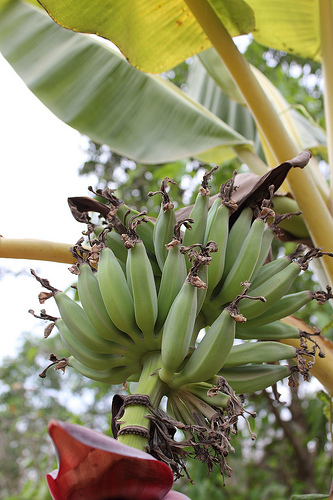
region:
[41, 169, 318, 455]
small green plant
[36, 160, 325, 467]
tipburn of green plant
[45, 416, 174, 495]
red leaf of plant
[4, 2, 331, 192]
big plantan leaves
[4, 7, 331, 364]
yellow branches with big leaves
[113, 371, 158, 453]
green thin stem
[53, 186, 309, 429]
green bunch of bananas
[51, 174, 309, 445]
green bunch of bananas with buntips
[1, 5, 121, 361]
white sky in the back of plants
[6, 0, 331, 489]
banana tree in a sunny day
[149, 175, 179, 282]
The banana is not yet ready to pick.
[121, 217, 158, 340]
The banana is not yet ready to pick.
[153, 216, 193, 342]
The banana is not yet ready to pick.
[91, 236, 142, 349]
The banana is not yet ready to pick.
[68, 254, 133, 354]
The banana is not yet ready to pick.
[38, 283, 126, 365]
The banana is not yet ready to pick.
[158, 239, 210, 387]
The banana is not yet ready to pick.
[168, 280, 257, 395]
The banana is not yet ready to pick.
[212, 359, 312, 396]
The banana is not yet ready to pick.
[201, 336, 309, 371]
The banana is not yet ready to pick.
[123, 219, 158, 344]
banana on a tree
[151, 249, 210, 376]
banana on a tree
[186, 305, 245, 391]
banana on a tree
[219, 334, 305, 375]
banana on a tree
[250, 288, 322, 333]
banana on a tree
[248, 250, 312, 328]
banana on a tree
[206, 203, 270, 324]
banana on a tree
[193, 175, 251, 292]
banana on a tree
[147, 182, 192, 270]
banana on a tree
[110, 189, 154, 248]
banana on a tree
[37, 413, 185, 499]
red leaf at bottom of tree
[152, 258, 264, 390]
first cluster of bananas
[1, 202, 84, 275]
Yellow horizontal stem on left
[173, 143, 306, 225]
Dried leaf on top right of bananas.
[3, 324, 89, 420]
Blurred leaves in the background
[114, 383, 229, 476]
Dried branches on bottom of bunch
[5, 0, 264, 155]
Large yellow and green leaves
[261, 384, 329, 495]
Tree in background behind bunches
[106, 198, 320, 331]
Top bunch of bananas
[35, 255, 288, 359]
Middle bunch of bananas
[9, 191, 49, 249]
The sky is white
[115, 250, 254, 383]
The fruit is growing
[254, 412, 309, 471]
The leaves are green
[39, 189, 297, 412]
The fruit are together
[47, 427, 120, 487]
The leaf is red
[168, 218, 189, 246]
Dark objects are at the end of the fruit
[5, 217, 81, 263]
The vine is yellow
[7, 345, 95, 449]
Trees are in the back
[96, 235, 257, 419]
The fruit is green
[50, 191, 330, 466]
Many bananas together